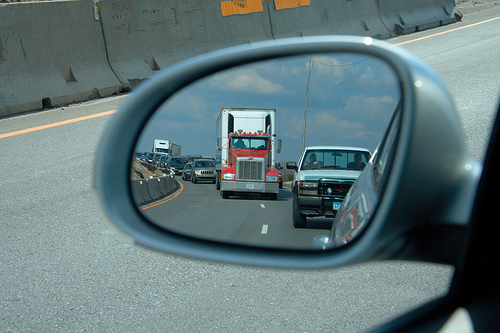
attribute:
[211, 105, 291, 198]
semi — red, white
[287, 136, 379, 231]
car — white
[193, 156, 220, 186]
car — gold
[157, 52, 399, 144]
sky — blue, cloudy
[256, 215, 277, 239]
stripes — white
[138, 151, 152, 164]
car — gray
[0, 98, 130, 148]
line — yellow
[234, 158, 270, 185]
grill — silver, metal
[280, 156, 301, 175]
mirror — black